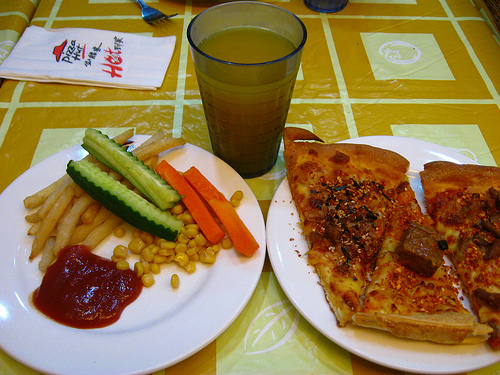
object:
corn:
[140, 272, 155, 289]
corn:
[150, 263, 160, 274]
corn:
[200, 250, 215, 264]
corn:
[128, 237, 147, 254]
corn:
[169, 274, 181, 290]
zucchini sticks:
[77, 125, 184, 214]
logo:
[52, 39, 103, 66]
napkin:
[1, 25, 176, 92]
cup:
[175, 1, 312, 180]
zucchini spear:
[64, 160, 184, 238]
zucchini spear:
[83, 121, 179, 212]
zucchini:
[59, 155, 186, 246]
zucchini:
[81, 126, 178, 211]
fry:
[78, 214, 119, 250]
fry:
[81, 202, 96, 224]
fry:
[52, 191, 93, 256]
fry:
[23, 184, 72, 269]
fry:
[18, 171, 72, 206]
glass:
[187, 0, 307, 178]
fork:
[133, 0, 181, 33]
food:
[13, 120, 259, 287]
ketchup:
[31, 243, 142, 330]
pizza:
[420, 160, 500, 352]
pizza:
[282, 126, 496, 347]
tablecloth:
[290, 47, 495, 172]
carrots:
[149, 156, 226, 245]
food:
[279, 127, 484, 346]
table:
[2, 2, 499, 374]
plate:
[0, 135, 266, 375]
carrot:
[182, 166, 259, 259]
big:
[40, 268, 132, 329]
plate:
[266, 135, 500, 375]